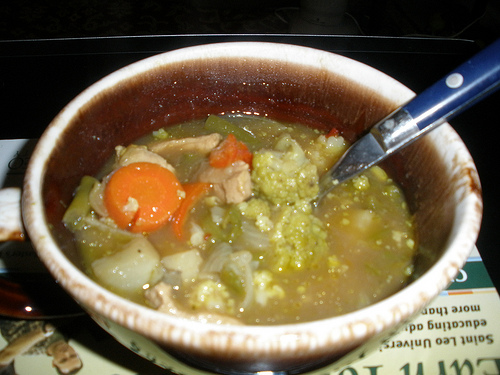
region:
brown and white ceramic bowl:
[18, 37, 488, 372]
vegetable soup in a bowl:
[93, 107, 423, 344]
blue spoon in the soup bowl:
[311, 29, 498, 213]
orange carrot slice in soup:
[105, 161, 182, 231]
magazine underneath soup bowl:
[3, 130, 498, 369]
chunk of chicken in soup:
[217, 171, 258, 208]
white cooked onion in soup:
[203, 239, 232, 278]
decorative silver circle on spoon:
[443, 71, 465, 91]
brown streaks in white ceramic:
[439, 148, 484, 215]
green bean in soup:
[202, 111, 256, 148]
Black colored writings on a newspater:
[425, 304, 476, 351]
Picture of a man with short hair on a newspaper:
[0, 324, 90, 373]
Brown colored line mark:
[445, 289, 477, 298]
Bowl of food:
[17, 37, 470, 366]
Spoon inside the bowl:
[298, 60, 478, 197]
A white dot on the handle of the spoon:
[430, 61, 475, 112]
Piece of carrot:
[105, 162, 181, 232]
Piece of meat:
[191, 163, 257, 198]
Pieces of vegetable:
[260, 140, 330, 270]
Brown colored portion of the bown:
[148, 69, 351, 127]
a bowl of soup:
[24, 28, 492, 367]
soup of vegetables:
[61, 90, 426, 329]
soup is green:
[70, 99, 429, 325]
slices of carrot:
[101, 125, 263, 244]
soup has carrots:
[76, 95, 418, 342]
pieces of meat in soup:
[186, 157, 264, 216]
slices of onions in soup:
[205, 217, 274, 314]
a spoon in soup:
[294, 47, 497, 192]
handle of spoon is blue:
[373, 45, 499, 152]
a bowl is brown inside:
[14, 32, 493, 365]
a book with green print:
[365, 243, 487, 372]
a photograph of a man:
[5, 288, 111, 371]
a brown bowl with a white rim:
[10, 51, 487, 367]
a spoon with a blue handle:
[285, 49, 499, 153]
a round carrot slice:
[95, 148, 188, 243]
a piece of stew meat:
[193, 151, 256, 214]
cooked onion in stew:
[193, 235, 240, 295]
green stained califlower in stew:
[248, 142, 318, 197]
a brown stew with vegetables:
[50, 78, 429, 303]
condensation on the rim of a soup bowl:
[187, 56, 342, 117]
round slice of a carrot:
[97, 152, 199, 232]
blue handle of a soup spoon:
[397, 13, 494, 105]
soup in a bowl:
[120, 121, 367, 293]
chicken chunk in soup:
[215, 150, 257, 230]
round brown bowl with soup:
[45, 65, 482, 374]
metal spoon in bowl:
[285, 35, 492, 194]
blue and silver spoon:
[404, 43, 494, 134]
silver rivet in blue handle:
[438, 57, 468, 103]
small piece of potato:
[97, 227, 172, 290]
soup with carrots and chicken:
[143, 110, 369, 342]